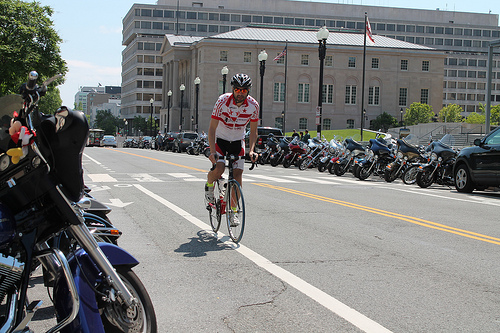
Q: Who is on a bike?
A: Man in white shirt.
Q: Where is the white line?
A: On road.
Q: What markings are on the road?
A: Lines.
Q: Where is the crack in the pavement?
A: In front of the cyclist.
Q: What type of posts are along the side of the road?
A: Light posts.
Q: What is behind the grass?
A: Buildings.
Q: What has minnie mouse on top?
A: A motorcycle.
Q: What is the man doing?
A: Riding a bike.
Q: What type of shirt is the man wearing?
A: A jersey.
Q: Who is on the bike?
A: A man.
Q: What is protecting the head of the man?
A: A helmet.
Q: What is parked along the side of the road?
A: Motorcycles.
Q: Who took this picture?
A: A spectator.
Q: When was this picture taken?
A: The afternoon.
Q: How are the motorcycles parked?
A: Backed in.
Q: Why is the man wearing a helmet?
A: For safety.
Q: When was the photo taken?
A: Daytime.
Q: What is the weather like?
A: Calm.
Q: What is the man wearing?
A: Clothes.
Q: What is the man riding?
A: A bike.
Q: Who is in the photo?
A: A man.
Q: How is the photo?
A: Clear.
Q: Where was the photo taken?
A: On the road.